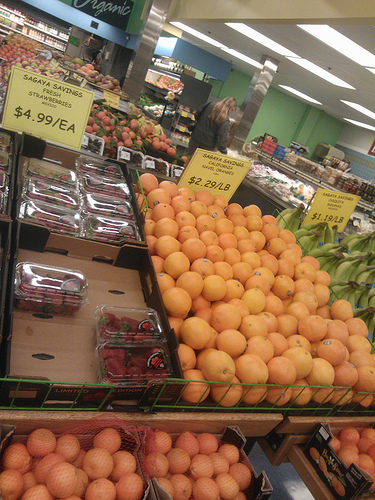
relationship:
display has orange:
[124, 143, 363, 416] [212, 324, 250, 359]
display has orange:
[124, 143, 363, 416] [276, 344, 316, 382]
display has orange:
[124, 143, 363, 416] [313, 333, 349, 368]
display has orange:
[124, 143, 363, 416] [270, 272, 297, 301]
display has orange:
[124, 143, 363, 416] [188, 253, 217, 278]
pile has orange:
[133, 168, 364, 404] [261, 355, 301, 386]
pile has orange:
[133, 168, 364, 404] [313, 333, 349, 368]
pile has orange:
[133, 168, 364, 404] [212, 324, 250, 359]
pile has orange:
[133, 168, 364, 404] [295, 312, 329, 344]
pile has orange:
[133, 168, 364, 404] [197, 225, 221, 250]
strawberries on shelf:
[92, 302, 166, 345] [0, 166, 373, 434]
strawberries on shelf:
[11, 259, 90, 316] [0, 166, 373, 434]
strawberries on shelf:
[83, 209, 142, 244] [0, 166, 373, 434]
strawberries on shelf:
[15, 196, 85, 239] [0, 166, 373, 434]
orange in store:
[148, 188, 171, 207] [3, 1, 367, 490]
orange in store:
[153, 203, 174, 222] [3, 1, 367, 490]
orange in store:
[180, 235, 206, 260] [3, 1, 367, 490]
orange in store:
[202, 274, 226, 300] [3, 1, 367, 490]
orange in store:
[211, 303, 241, 332] [3, 1, 367, 490]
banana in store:
[274, 200, 306, 229] [3, 1, 367, 490]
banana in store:
[332, 253, 363, 285] [3, 1, 367, 490]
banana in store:
[289, 218, 334, 256] [3, 1, 367, 490]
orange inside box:
[240, 281, 267, 313] [127, 160, 363, 407]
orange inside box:
[172, 265, 206, 301] [127, 160, 363, 407]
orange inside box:
[214, 324, 250, 356] [127, 160, 363, 407]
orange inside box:
[269, 269, 295, 302] [127, 160, 363, 407]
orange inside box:
[291, 258, 317, 285] [127, 160, 363, 407]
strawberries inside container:
[95, 309, 163, 341] [90, 302, 167, 349]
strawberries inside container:
[97, 339, 172, 376] [89, 337, 177, 386]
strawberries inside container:
[14, 259, 87, 320] [8, 258, 90, 320]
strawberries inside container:
[84, 212, 137, 243] [77, 207, 143, 246]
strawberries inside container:
[21, 193, 80, 233] [69, 151, 126, 183]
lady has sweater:
[190, 93, 234, 157] [191, 101, 233, 141]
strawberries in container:
[83, 300, 154, 336] [94, 302, 163, 347]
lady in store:
[185, 94, 238, 159] [3, 1, 367, 490]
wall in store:
[210, 64, 347, 160] [3, 1, 367, 490]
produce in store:
[4, 38, 372, 496] [3, 1, 367, 490]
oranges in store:
[149, 188, 168, 217] [9, 13, 360, 466]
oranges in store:
[159, 206, 182, 238] [9, 13, 360, 466]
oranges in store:
[177, 195, 207, 226] [9, 13, 360, 466]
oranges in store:
[189, 227, 230, 257] [9, 13, 360, 466]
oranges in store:
[207, 222, 243, 250] [9, 13, 360, 466]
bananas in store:
[279, 203, 374, 323] [3, 1, 367, 490]